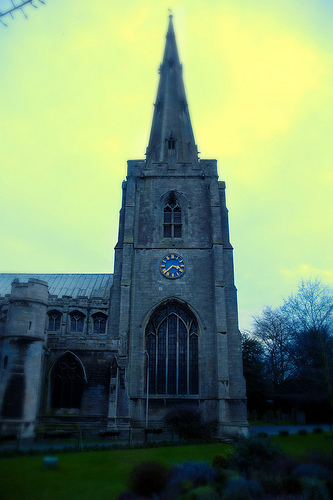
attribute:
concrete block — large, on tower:
[222, 400, 248, 424]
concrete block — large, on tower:
[229, 397, 247, 427]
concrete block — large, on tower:
[130, 398, 146, 418]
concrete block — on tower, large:
[229, 397, 247, 423]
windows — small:
[152, 55, 191, 153]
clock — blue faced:
[156, 249, 183, 281]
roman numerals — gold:
[158, 250, 187, 277]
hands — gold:
[161, 261, 180, 277]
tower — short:
[4, 279, 52, 442]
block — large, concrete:
[208, 288, 241, 340]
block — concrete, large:
[108, 282, 146, 363]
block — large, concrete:
[121, 154, 221, 179]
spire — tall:
[147, 33, 195, 148]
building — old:
[155, 215, 217, 475]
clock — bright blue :
[152, 254, 194, 288]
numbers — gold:
[166, 254, 179, 273]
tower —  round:
[0, 272, 46, 449]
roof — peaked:
[15, 264, 110, 296]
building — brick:
[3, 290, 110, 375]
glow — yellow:
[1, 2, 320, 303]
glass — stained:
[139, 293, 200, 396]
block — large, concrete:
[213, 332, 228, 383]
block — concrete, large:
[210, 243, 226, 289]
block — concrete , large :
[209, 200, 228, 250]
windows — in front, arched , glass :
[142, 297, 206, 399]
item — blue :
[39, 450, 62, 465]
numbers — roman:
[161, 252, 182, 279]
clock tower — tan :
[104, 10, 253, 443]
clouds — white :
[120, 14, 313, 201]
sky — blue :
[1, 0, 330, 379]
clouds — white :
[234, 201, 307, 247]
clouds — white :
[194, 16, 244, 83]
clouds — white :
[4, 139, 60, 199]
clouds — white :
[3, 116, 79, 216]